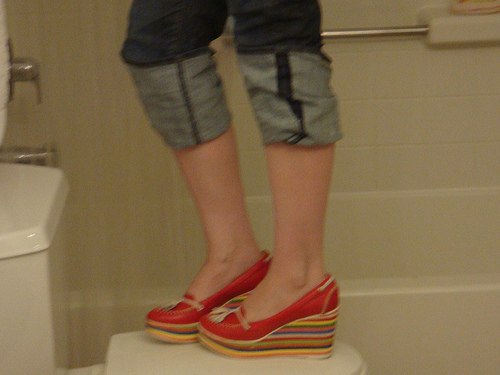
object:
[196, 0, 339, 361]
legs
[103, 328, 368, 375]
lid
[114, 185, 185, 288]
tile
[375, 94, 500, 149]
grey tile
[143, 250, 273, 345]
shoe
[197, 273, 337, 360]
shoe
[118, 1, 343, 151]
jeans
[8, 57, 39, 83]
knob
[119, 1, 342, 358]
person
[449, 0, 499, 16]
soap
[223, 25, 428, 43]
bar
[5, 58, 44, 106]
handle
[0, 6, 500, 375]
wall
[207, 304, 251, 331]
cording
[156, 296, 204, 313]
cording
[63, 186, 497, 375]
bathtub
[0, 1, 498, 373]
bathroom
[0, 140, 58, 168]
faucet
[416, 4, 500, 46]
soap dish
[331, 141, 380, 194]
tiled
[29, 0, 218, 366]
curtain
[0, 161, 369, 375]
toilet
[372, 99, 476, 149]
tile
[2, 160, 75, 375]
cistern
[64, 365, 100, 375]
hose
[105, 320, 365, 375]
seat